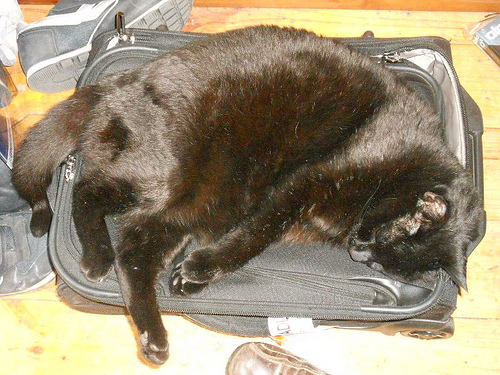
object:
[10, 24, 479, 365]
cat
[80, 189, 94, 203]
black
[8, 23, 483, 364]
lying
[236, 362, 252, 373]
brown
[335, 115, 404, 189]
on cat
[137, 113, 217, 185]
on cat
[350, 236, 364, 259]
nose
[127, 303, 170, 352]
long feet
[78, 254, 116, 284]
paws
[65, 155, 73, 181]
zipper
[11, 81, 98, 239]
tail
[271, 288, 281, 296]
black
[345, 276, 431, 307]
on suitcase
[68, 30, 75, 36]
black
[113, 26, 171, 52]
above suitcase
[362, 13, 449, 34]
wood floor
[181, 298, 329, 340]
front of suitcase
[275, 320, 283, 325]
white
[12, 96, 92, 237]
of cat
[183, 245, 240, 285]
front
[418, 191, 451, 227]
ears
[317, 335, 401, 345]
next to bag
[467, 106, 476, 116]
grey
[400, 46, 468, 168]
in bag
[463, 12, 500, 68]
book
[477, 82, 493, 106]
floor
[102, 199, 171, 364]
leg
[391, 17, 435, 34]
in flooring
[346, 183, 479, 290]
head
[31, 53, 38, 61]
gray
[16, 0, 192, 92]
shoe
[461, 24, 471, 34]
corner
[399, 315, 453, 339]
wheel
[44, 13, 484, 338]
bag